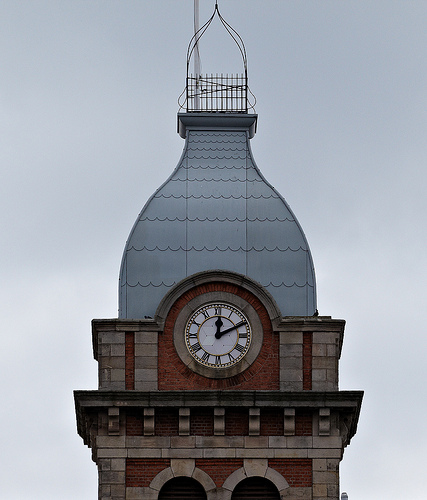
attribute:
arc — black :
[155, 465, 208, 498]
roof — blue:
[114, 109, 320, 323]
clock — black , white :
[184, 299, 252, 367]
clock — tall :
[153, 283, 282, 379]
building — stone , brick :
[72, 1, 364, 498]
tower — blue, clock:
[67, 109, 364, 498]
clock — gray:
[166, 298, 268, 375]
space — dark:
[150, 472, 216, 498]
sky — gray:
[285, 53, 398, 133]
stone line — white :
[277, 328, 306, 389]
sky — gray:
[247, 2, 424, 317]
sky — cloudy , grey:
[2, 0, 425, 498]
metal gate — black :
[167, 73, 315, 129]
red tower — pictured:
[72, 276, 357, 497]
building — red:
[7, 12, 412, 491]